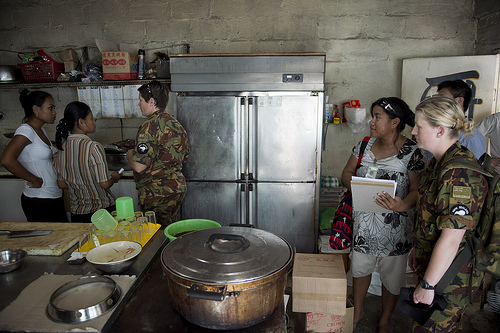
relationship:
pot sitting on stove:
[162, 230, 293, 330] [105, 234, 284, 332]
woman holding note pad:
[341, 96, 420, 329] [350, 175, 396, 215]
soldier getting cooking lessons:
[126, 81, 190, 231] [6, 77, 190, 228]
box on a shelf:
[95, 37, 139, 79] [1, 82, 172, 86]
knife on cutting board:
[1, 228, 53, 240] [0, 223, 96, 256]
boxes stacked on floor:
[292, 252, 355, 332] [285, 280, 431, 333]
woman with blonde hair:
[410, 98, 498, 331] [414, 96, 473, 137]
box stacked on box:
[292, 251, 346, 315] [300, 299, 356, 332]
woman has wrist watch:
[410, 98, 498, 331] [419, 278, 433, 290]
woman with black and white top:
[341, 96, 420, 329] [351, 135, 422, 255]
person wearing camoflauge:
[410, 98, 498, 331] [415, 143, 498, 332]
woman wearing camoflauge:
[126, 81, 190, 231] [134, 112, 192, 226]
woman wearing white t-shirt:
[2, 89, 68, 222] [14, 125, 63, 200]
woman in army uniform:
[410, 98, 498, 331] [415, 143, 498, 332]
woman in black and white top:
[341, 96, 420, 329] [351, 135, 422, 255]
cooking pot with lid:
[162, 230, 293, 330] [163, 226, 291, 283]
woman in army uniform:
[126, 81, 190, 231] [134, 112, 192, 226]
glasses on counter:
[96, 204, 155, 245] [1, 223, 169, 333]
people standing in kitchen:
[1, 81, 498, 331] [0, 0, 498, 331]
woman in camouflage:
[410, 98, 498, 331] [415, 143, 498, 332]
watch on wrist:
[419, 278, 433, 290] [416, 273, 438, 297]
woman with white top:
[2, 89, 68, 222] [14, 125, 63, 200]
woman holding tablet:
[341, 96, 420, 329] [350, 175, 396, 215]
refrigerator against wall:
[168, 54, 318, 255] [0, 2, 499, 183]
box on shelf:
[95, 37, 139, 79] [1, 82, 172, 86]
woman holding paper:
[341, 96, 420, 329] [350, 175, 396, 215]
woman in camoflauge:
[410, 98, 498, 331] [415, 143, 498, 332]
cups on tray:
[96, 204, 155, 245] [73, 217, 160, 259]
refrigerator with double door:
[168, 54, 318, 255] [175, 94, 315, 252]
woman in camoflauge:
[126, 81, 190, 231] [134, 112, 192, 226]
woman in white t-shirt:
[2, 89, 68, 222] [14, 125, 63, 200]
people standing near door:
[342, 80, 499, 332] [400, 53, 498, 159]